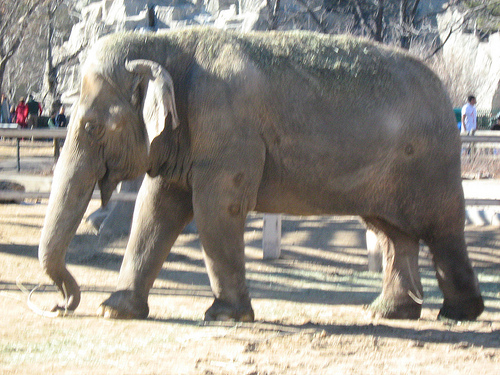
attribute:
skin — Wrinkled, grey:
[105, 128, 192, 180]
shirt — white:
[454, 105, 484, 133]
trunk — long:
[39, 162, 108, 324]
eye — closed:
[81, 117, 99, 134]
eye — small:
[79, 114, 100, 138]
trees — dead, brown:
[0, 1, 57, 116]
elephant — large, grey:
[46, 17, 476, 315]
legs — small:
[437, 239, 481, 320]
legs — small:
[374, 244, 416, 316]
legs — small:
[191, 172, 255, 320]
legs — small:
[108, 180, 188, 317]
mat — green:
[152, 21, 422, 95]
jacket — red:
[15, 102, 26, 124]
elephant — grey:
[64, 23, 459, 269]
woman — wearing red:
[0, 81, 41, 128]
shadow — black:
[179, 202, 390, 300]